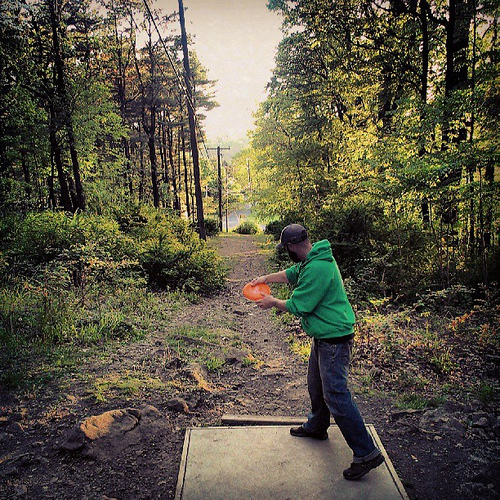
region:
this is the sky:
[210, 21, 248, 56]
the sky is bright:
[210, 19, 257, 69]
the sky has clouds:
[221, 49, 251, 95]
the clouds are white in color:
[225, 52, 247, 99]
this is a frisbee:
[240, 283, 273, 300]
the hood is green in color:
[305, 264, 340, 319]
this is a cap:
[268, 224, 310, 247]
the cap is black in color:
[287, 225, 297, 237]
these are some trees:
[12, 5, 197, 257]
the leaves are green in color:
[87, 96, 113, 130]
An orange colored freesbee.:
[239, 275, 274, 307]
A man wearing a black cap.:
[273, 224, 313, 266]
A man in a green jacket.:
[232, 221, 389, 491]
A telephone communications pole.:
[208, 137, 230, 233]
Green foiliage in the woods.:
[41, 75, 181, 259]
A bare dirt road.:
[227, 244, 279, 404]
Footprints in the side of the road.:
[34, 389, 160, 470]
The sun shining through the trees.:
[341, 89, 496, 234]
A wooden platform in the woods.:
[169, 419, 409, 499]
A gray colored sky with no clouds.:
[212, 40, 252, 163]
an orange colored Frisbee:
[240, 278, 271, 300]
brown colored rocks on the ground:
[60, 400, 161, 463]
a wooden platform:
[170, 419, 409, 499]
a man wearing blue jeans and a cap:
[241, 223, 386, 481]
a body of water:
[210, 207, 275, 234]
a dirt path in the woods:
[1, 230, 466, 497]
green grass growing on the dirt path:
[82, 316, 224, 406]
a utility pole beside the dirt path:
[206, 142, 229, 232]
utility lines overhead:
[131, 1, 233, 159]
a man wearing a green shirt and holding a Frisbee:
[240, 221, 382, 481]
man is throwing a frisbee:
[232, 218, 387, 483]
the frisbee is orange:
[240, 275, 270, 301]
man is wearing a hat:
[273, 219, 310, 248]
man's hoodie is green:
[281, 237, 368, 344]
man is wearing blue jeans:
[296, 334, 377, 459]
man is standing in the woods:
[0, 4, 499, 498]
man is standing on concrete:
[166, 217, 413, 499]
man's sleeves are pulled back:
[253, 262, 307, 322]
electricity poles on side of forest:
[34, 1, 236, 235]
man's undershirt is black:
[324, 330, 359, 346]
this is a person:
[240, 218, 385, 481]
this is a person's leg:
[317, 345, 382, 483]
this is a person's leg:
[291, 338, 331, 450]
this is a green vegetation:
[8, 281, 95, 360]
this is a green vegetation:
[25, 200, 93, 279]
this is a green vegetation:
[138, 204, 220, 285]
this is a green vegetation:
[346, 193, 433, 279]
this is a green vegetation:
[72, 99, 127, 193]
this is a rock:
[68, 405, 173, 470]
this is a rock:
[165, 389, 198, 416]